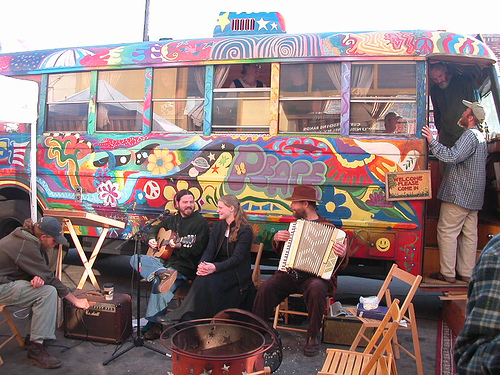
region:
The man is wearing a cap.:
[462, 100, 484, 122]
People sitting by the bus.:
[138, 193, 337, 294]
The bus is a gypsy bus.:
[43, 131, 401, 209]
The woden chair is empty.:
[325, 291, 407, 366]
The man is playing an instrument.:
[266, 179, 340, 328]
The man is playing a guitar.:
[135, 219, 205, 255]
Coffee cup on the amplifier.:
[99, 273, 126, 303]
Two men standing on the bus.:
[425, 75, 482, 264]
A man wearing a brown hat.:
[269, 179, 342, 203]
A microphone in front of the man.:
[121, 203, 177, 358]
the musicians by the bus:
[130, 183, 350, 350]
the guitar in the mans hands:
[146, 226, 196, 259]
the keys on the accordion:
[273, 219, 304, 271]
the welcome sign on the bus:
[381, 159, 431, 208]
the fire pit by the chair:
[163, 319, 276, 374]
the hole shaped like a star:
[219, 361, 234, 373]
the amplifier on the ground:
[65, 284, 134, 346]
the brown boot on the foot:
[21, 340, 69, 374]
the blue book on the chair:
[359, 298, 394, 324]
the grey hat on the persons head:
[34, 215, 68, 249]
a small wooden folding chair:
[320, 311, 401, 373]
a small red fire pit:
[157, 299, 272, 374]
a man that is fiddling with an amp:
[6, 209, 111, 374]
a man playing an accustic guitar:
[135, 200, 203, 271]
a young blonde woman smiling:
[200, 192, 252, 290]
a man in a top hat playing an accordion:
[267, 181, 359, 337]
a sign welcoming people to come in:
[376, 145, 442, 208]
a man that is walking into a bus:
[415, 102, 492, 282]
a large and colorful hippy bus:
[5, 33, 486, 250]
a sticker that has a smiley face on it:
[362, 229, 399, 259]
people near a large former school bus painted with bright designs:
[0, 10, 498, 365]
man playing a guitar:
[145, 187, 197, 255]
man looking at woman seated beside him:
[130, 187, 251, 330]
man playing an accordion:
[268, 183, 344, 279]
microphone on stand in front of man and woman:
[101, 190, 251, 366]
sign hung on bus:
[382, 150, 430, 196]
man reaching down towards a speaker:
[0, 215, 130, 365]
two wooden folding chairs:
[318, 260, 423, 371]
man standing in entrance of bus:
[420, 53, 496, 285]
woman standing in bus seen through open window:
[210, 59, 272, 131]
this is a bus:
[2, 37, 497, 249]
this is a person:
[1, 216, 98, 371]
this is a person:
[166, 186, 262, 325]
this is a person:
[117, 182, 207, 327]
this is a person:
[260, 172, 348, 359]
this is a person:
[408, 88, 495, 293]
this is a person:
[418, 54, 488, 203]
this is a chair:
[314, 293, 410, 371]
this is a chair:
[346, 263, 439, 358]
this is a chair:
[196, 216, 273, 318]